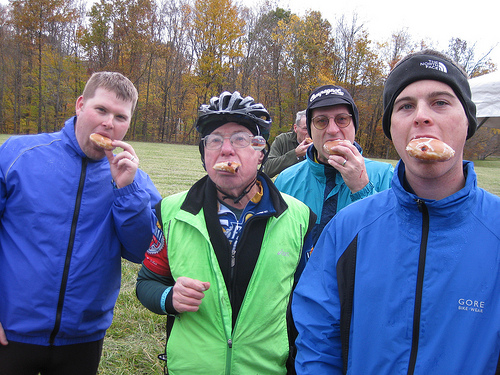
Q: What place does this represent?
A: It represents the field.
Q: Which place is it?
A: It is a field.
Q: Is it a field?
A: Yes, it is a field.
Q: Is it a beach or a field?
A: It is a field.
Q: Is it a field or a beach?
A: It is a field.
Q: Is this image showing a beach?
A: No, the picture is showing a field.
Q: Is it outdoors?
A: Yes, it is outdoors.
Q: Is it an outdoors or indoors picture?
A: It is outdoors.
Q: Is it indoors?
A: No, it is outdoors.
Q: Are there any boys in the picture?
A: No, there are no boys.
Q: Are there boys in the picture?
A: No, there are no boys.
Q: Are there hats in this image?
A: Yes, there is a hat.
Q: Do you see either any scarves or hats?
A: Yes, there is a hat.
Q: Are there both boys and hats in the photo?
A: No, there is a hat but no boys.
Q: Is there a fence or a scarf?
A: No, there are no fences or scarves.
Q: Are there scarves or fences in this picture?
A: No, there are no fences or scarves.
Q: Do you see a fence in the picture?
A: No, there are no fences.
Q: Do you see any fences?
A: No, there are no fences.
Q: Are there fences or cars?
A: No, there are no fences or cars.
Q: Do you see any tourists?
A: No, there are no tourists.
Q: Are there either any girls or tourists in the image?
A: No, there are no tourists or girls.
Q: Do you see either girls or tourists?
A: No, there are no tourists or girls.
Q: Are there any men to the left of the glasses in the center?
A: Yes, there are men to the left of the glasses.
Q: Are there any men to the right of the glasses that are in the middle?
A: No, the men are to the left of the glasses.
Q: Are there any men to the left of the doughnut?
A: Yes, there are men to the left of the doughnut.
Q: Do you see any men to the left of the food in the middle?
A: Yes, there are men to the left of the doughnut.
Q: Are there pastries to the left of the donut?
A: No, there are men to the left of the donut.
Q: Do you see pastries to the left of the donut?
A: No, there are men to the left of the donut.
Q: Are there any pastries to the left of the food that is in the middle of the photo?
A: No, there are men to the left of the donut.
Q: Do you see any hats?
A: Yes, there is a hat.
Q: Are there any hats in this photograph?
A: Yes, there is a hat.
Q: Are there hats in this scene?
A: Yes, there is a hat.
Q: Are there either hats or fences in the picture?
A: Yes, there is a hat.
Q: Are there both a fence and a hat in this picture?
A: No, there is a hat but no fences.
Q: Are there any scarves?
A: No, there are no scarves.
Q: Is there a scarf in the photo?
A: No, there are no scarves.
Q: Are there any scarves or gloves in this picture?
A: No, there are no scarves or gloves.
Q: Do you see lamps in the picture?
A: No, there are no lamps.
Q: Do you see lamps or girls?
A: No, there are no lamps or girls.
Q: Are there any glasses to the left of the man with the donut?
A: Yes, there are glasses to the left of the man.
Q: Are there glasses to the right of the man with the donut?
A: No, the glasses are to the left of the man.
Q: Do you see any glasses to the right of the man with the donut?
A: No, the glasses are to the left of the man.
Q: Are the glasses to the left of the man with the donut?
A: Yes, the glasses are to the left of the man.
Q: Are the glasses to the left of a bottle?
A: No, the glasses are to the left of the man.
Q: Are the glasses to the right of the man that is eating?
A: No, the glasses are to the left of the man.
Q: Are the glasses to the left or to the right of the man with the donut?
A: The glasses are to the left of the man.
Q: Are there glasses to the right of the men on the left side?
A: Yes, there are glasses to the right of the men.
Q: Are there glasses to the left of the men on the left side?
A: No, the glasses are to the right of the men.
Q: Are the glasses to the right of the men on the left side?
A: Yes, the glasses are to the right of the men.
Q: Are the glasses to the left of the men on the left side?
A: No, the glasses are to the right of the men.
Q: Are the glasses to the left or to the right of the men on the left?
A: The glasses are to the right of the men.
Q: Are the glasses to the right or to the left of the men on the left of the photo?
A: The glasses are to the right of the men.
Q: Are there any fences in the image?
A: No, there are no fences.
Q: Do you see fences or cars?
A: No, there are no fences or cars.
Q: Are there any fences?
A: No, there are no fences.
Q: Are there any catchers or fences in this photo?
A: No, there are no fences or catchers.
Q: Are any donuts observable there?
A: Yes, there is a donut.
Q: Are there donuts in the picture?
A: Yes, there is a donut.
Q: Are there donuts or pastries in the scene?
A: Yes, there is a donut.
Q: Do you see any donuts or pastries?
A: Yes, there is a donut.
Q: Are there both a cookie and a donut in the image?
A: No, there is a donut but no cookies.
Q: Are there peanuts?
A: No, there are no peanuts.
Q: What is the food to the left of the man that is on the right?
A: The food is a donut.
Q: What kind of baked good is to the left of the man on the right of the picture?
A: The food is a donut.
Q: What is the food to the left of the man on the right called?
A: The food is a donut.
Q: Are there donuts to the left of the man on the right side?
A: Yes, there is a donut to the left of the man.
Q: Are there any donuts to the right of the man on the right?
A: No, the donut is to the left of the man.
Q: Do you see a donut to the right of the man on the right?
A: No, the donut is to the left of the man.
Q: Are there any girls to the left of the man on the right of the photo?
A: No, there is a donut to the left of the man.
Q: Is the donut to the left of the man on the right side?
A: Yes, the donut is to the left of the man.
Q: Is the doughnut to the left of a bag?
A: No, the doughnut is to the left of the man.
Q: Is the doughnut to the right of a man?
A: No, the doughnut is to the left of a man.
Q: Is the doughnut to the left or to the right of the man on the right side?
A: The doughnut is to the left of the man.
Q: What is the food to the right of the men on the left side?
A: The food is a donut.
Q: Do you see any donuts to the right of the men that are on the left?
A: Yes, there is a donut to the right of the men.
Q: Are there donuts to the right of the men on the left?
A: Yes, there is a donut to the right of the men.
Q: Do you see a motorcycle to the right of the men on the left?
A: No, there is a donut to the right of the men.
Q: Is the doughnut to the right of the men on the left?
A: Yes, the doughnut is to the right of the men.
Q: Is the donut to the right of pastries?
A: No, the donut is to the right of the men.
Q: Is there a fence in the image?
A: No, there are no fences.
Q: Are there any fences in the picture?
A: No, there are no fences.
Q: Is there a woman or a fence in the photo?
A: No, there are no fences or women.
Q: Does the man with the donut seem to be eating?
A: Yes, the man is eating.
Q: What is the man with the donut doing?
A: The man is eating.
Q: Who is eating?
A: The man is eating.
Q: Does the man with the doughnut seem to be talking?
A: No, the man is eating.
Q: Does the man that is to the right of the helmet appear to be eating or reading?
A: The man is eating.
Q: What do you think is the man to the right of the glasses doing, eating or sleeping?
A: The man is eating.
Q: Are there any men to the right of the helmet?
A: Yes, there is a man to the right of the helmet.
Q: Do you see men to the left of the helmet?
A: No, the man is to the right of the helmet.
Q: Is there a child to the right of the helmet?
A: No, there is a man to the right of the helmet.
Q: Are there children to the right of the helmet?
A: No, there is a man to the right of the helmet.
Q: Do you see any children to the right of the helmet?
A: No, there is a man to the right of the helmet.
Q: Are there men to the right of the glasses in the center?
A: Yes, there is a man to the right of the glasses.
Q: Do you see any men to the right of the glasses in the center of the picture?
A: Yes, there is a man to the right of the glasses.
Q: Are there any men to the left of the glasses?
A: No, the man is to the right of the glasses.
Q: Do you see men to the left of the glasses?
A: No, the man is to the right of the glasses.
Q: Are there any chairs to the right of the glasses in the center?
A: No, there is a man to the right of the glasses.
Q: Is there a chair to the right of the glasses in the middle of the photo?
A: No, there is a man to the right of the glasses.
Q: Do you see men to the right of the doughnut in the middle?
A: Yes, there is a man to the right of the donut.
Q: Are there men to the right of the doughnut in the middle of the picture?
A: Yes, there is a man to the right of the donut.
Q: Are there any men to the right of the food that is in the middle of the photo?
A: Yes, there is a man to the right of the donut.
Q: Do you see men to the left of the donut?
A: No, the man is to the right of the donut.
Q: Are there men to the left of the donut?
A: No, the man is to the right of the donut.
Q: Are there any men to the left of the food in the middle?
A: No, the man is to the right of the donut.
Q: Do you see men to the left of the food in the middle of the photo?
A: No, the man is to the right of the donut.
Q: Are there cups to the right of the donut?
A: No, there is a man to the right of the donut.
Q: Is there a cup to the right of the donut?
A: No, there is a man to the right of the donut.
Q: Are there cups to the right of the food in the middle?
A: No, there is a man to the right of the donut.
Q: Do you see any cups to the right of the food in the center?
A: No, there is a man to the right of the donut.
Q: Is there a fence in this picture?
A: No, there are no fences.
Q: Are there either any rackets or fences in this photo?
A: No, there are no fences or rackets.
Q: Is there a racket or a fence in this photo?
A: No, there are no fences or rackets.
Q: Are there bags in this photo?
A: No, there are no bags.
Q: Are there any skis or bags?
A: No, there are no bags or skis.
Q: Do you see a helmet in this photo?
A: Yes, there is a helmet.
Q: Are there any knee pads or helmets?
A: Yes, there is a helmet.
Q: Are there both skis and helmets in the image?
A: No, there is a helmet but no skis.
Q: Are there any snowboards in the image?
A: No, there are no snowboards.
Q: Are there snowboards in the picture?
A: No, there are no snowboards.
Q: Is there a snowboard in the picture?
A: No, there are no snowboards.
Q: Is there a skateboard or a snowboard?
A: No, there are no snowboards or skateboards.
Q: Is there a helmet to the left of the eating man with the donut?
A: Yes, there is a helmet to the left of the man.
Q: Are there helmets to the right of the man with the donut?
A: No, the helmet is to the left of the man.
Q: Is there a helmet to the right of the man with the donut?
A: No, the helmet is to the left of the man.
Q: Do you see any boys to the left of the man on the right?
A: No, there is a helmet to the left of the man.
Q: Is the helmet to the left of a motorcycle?
A: No, the helmet is to the left of the man.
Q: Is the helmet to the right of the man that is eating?
A: No, the helmet is to the left of the man.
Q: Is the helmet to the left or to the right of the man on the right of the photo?
A: The helmet is to the left of the man.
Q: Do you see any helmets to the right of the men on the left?
A: Yes, there is a helmet to the right of the men.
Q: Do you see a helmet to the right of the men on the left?
A: Yes, there is a helmet to the right of the men.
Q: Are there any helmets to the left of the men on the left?
A: No, the helmet is to the right of the men.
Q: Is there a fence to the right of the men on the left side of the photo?
A: No, there is a helmet to the right of the men.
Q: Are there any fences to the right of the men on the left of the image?
A: No, there is a helmet to the right of the men.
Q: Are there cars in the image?
A: No, there are no cars.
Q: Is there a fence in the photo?
A: No, there are no fences.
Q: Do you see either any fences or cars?
A: No, there are no fences or cars.